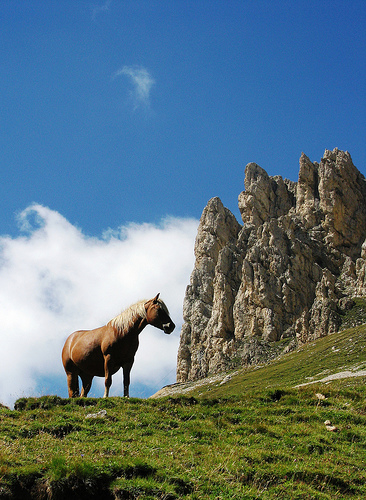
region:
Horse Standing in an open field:
[47, 282, 196, 411]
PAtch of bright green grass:
[7, 444, 69, 497]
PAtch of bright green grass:
[68, 443, 111, 494]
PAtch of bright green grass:
[100, 442, 150, 496]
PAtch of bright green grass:
[138, 440, 182, 499]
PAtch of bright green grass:
[167, 428, 221, 497]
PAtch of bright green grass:
[211, 432, 258, 498]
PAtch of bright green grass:
[240, 435, 297, 499]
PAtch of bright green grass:
[282, 433, 335, 496]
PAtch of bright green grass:
[126, 396, 347, 491]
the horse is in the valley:
[73, 313, 189, 387]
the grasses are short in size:
[213, 409, 306, 493]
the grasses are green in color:
[188, 406, 300, 470]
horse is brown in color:
[63, 307, 179, 397]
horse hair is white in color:
[98, 289, 157, 325]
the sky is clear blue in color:
[153, 175, 197, 196]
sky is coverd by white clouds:
[80, 238, 159, 275]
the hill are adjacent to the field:
[225, 205, 337, 300]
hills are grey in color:
[220, 213, 335, 326]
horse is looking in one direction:
[67, 287, 221, 386]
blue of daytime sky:
[3, 0, 363, 236]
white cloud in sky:
[5, 202, 198, 397]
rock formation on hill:
[176, 149, 362, 381]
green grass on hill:
[3, 332, 362, 496]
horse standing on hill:
[61, 297, 174, 397]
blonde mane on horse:
[105, 303, 149, 337]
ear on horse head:
[152, 292, 162, 305]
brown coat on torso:
[70, 328, 116, 374]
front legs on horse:
[103, 355, 135, 395]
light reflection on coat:
[65, 330, 82, 355]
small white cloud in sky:
[95, 39, 180, 122]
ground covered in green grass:
[130, 411, 285, 498]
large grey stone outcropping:
[182, 146, 356, 321]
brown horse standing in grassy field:
[50, 291, 179, 410]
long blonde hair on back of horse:
[106, 292, 150, 340]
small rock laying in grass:
[314, 413, 340, 438]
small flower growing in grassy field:
[308, 389, 330, 417]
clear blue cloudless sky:
[211, 10, 363, 145]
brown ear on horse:
[147, 288, 161, 302]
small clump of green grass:
[21, 411, 90, 444]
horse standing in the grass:
[26, 281, 194, 443]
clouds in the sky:
[15, 229, 147, 325]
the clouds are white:
[14, 244, 78, 315]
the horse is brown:
[61, 312, 146, 390]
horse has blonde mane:
[108, 296, 152, 333]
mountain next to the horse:
[167, 228, 359, 393]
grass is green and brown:
[78, 397, 214, 468]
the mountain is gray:
[200, 231, 290, 310]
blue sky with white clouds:
[4, 227, 121, 382]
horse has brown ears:
[144, 280, 160, 306]